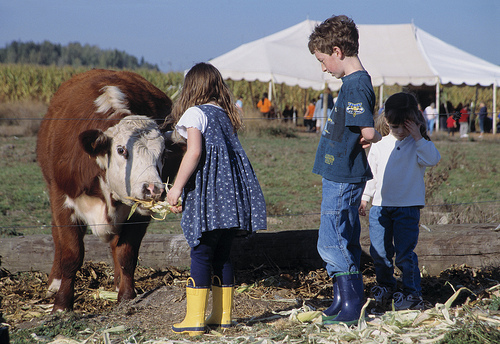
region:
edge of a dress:
[202, 205, 243, 243]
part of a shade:
[256, 227, 308, 302]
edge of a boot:
[338, 262, 361, 295]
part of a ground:
[248, 295, 285, 333]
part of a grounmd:
[258, 265, 291, 296]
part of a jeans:
[178, 238, 232, 305]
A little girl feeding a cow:
[20, 57, 266, 342]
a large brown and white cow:
[12, 56, 180, 304]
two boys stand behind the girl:
[273, 7, 452, 330]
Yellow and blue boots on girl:
[156, 270, 265, 342]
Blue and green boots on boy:
[320, 261, 397, 329]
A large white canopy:
[171, 8, 498, 142]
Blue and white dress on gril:
[159, 93, 282, 243]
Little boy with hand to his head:
[378, 89, 457, 293]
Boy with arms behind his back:
[309, 18, 386, 324]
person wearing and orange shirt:
[251, 89, 286, 126]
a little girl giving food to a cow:
[30, 42, 271, 341]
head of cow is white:
[83, 103, 175, 225]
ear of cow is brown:
[62, 125, 114, 165]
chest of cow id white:
[73, 200, 125, 247]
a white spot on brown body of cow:
[79, 71, 139, 127]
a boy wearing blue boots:
[290, 5, 385, 333]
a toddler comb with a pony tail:
[367, 82, 452, 313]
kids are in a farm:
[34, 3, 484, 338]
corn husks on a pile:
[316, 283, 498, 337]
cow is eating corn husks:
[84, 107, 193, 249]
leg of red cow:
[111, 233, 138, 302]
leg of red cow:
[56, 251, 83, 315]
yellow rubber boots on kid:
[158, 283, 245, 329]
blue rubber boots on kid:
[315, 267, 372, 328]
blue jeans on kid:
[368, 190, 432, 307]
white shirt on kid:
[356, 135, 430, 205]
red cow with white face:
[45, 67, 155, 297]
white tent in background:
[191, 20, 498, 128]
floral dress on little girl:
[171, 93, 269, 240]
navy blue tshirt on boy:
[312, 77, 371, 191]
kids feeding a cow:
[45, 4, 442, 321]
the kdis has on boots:
[146, 12, 446, 342]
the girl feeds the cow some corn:
[27, 43, 259, 338]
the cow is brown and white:
[38, 43, 185, 312]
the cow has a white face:
[97, 117, 195, 234]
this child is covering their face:
[360, 78, 460, 318]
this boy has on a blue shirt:
[279, 18, 382, 330]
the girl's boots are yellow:
[169, 263, 253, 334]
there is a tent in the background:
[203, 13, 499, 146]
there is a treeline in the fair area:
[3, 26, 238, 113]